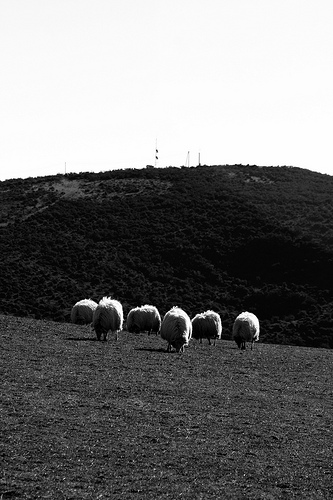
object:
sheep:
[92, 296, 125, 341]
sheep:
[124, 303, 161, 336]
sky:
[0, 0, 333, 181]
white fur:
[144, 310, 149, 317]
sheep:
[158, 304, 194, 352]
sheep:
[71, 298, 99, 326]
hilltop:
[2, 162, 330, 192]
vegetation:
[0, 161, 333, 356]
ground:
[0, 313, 333, 500]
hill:
[0, 161, 333, 347]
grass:
[0, 316, 333, 500]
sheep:
[231, 309, 262, 346]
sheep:
[191, 307, 224, 342]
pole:
[185, 149, 191, 169]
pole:
[155, 136, 159, 168]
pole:
[198, 151, 201, 166]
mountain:
[0, 155, 333, 343]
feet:
[104, 335, 109, 340]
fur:
[103, 304, 113, 320]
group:
[69, 295, 262, 356]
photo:
[0, 0, 333, 500]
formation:
[0, 161, 333, 349]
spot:
[26, 205, 35, 210]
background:
[0, 0, 333, 342]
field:
[0, 161, 333, 500]